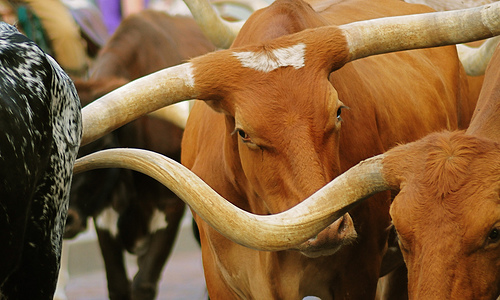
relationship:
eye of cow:
[231, 124, 253, 139] [71, 1, 499, 283]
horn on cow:
[70, 147, 397, 246] [72, 132, 497, 299]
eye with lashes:
[231, 124, 253, 139] [230, 128, 239, 137]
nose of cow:
[303, 214, 356, 258] [71, 1, 499, 283]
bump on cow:
[229, 1, 327, 49] [71, 1, 499, 283]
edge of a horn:
[68, 53, 198, 108] [81, 64, 195, 129]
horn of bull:
[70, 147, 397, 246] [388, 53, 497, 299]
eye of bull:
[231, 124, 253, 139] [71, 1, 499, 283]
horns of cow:
[61, 4, 499, 143] [71, 1, 499, 283]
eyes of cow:
[231, 100, 344, 139] [71, 1, 499, 283]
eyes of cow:
[385, 210, 498, 250] [72, 132, 497, 299]